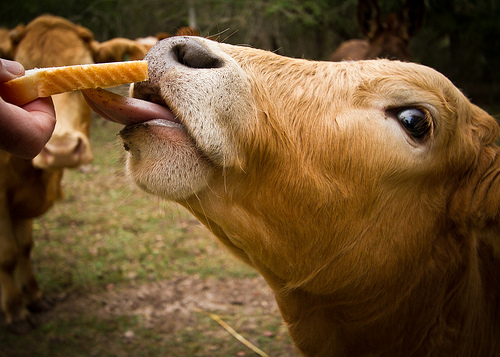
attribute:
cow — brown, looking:
[131, 33, 489, 320]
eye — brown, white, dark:
[381, 97, 446, 156]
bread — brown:
[4, 59, 167, 97]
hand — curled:
[2, 43, 57, 158]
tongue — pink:
[68, 88, 167, 130]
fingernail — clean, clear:
[2, 57, 24, 77]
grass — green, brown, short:
[77, 216, 198, 335]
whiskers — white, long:
[173, 113, 238, 218]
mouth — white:
[132, 69, 230, 186]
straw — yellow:
[206, 308, 263, 355]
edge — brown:
[3, 51, 154, 98]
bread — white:
[4, 48, 156, 105]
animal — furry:
[82, 32, 496, 353]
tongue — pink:
[78, 85, 173, 128]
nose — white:
[143, 27, 230, 93]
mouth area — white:
[104, 73, 215, 165]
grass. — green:
[12, 174, 254, 354]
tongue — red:
[84, 85, 169, 122]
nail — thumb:
[7, 57, 29, 77]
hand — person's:
[0, 54, 61, 156]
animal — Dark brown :
[330, 25, 408, 59]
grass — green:
[3, 117, 288, 349]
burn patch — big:
[45, 272, 281, 317]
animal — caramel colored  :
[0, 15, 145, 325]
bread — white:
[0, 58, 149, 105]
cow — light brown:
[101, 40, 450, 354]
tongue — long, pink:
[74, 82, 165, 135]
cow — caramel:
[82, 30, 489, 352]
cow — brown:
[124, 33, 498, 353]